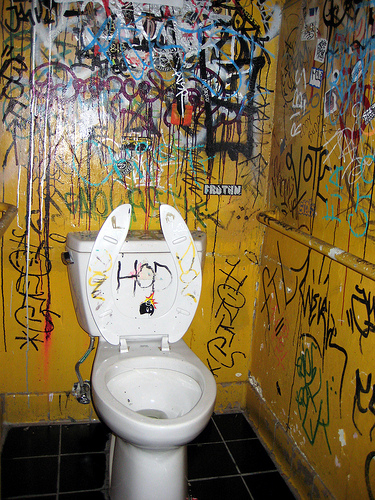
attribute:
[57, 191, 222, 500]
toilet — white, dirty, open, shallow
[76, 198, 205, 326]
graffiti — propped up, white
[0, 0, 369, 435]
walls — yellow, multicolored, dirty, scribbled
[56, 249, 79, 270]
handle — silver, metal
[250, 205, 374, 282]
rail — yellow, painted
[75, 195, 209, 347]
seat — painted, open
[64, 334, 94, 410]
pipe — silver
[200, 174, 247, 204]
sticker — black, white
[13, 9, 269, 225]
paint — runny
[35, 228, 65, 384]
paint — red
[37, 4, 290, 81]
paint — white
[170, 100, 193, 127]
sticker — yellow, red, fused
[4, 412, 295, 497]
floor — black, tiled